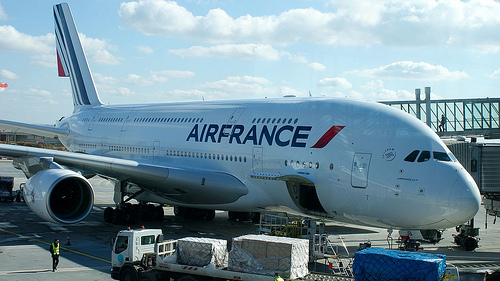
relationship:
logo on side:
[187, 118, 348, 147] [63, 95, 460, 223]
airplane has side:
[1, 0, 481, 238] [63, 95, 460, 223]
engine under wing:
[17, 168, 94, 227] [0, 139, 247, 220]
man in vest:
[50, 235, 63, 275] [50, 243, 61, 257]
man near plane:
[50, 235, 63, 275] [1, 0, 481, 238]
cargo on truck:
[175, 228, 313, 280] [109, 221, 356, 279]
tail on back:
[55, 4, 99, 113] [58, 110, 96, 154]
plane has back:
[1, 0, 481, 238] [58, 110, 96, 154]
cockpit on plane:
[401, 149, 457, 164] [1, 0, 481, 238]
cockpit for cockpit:
[401, 149, 457, 164] [397, 138, 457, 179]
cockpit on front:
[401, 149, 457, 164] [376, 115, 477, 223]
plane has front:
[1, 0, 481, 238] [376, 115, 477, 223]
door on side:
[351, 151, 370, 189] [63, 95, 460, 223]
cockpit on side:
[401, 149, 457, 164] [63, 95, 460, 223]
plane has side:
[1, 0, 481, 238] [63, 95, 460, 223]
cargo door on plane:
[250, 165, 325, 215] [1, 0, 481, 238]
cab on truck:
[113, 223, 163, 268] [109, 221, 356, 279]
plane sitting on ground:
[1, 0, 481, 238] [6, 155, 500, 273]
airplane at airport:
[1, 0, 481, 238] [4, 4, 499, 277]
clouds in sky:
[2, 7, 500, 109] [0, 0, 497, 126]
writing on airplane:
[187, 118, 348, 147] [1, 0, 481, 238]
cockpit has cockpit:
[397, 138, 457, 179] [401, 149, 457, 164]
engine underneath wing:
[17, 168, 94, 227] [0, 139, 247, 220]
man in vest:
[50, 239, 62, 272] [50, 243, 61, 257]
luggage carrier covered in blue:
[348, 244, 451, 278] [354, 249, 454, 276]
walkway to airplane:
[312, 227, 357, 278] [1, 0, 481, 238]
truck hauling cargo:
[109, 221, 356, 279] [175, 228, 313, 280]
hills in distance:
[30, 113, 61, 129] [2, 0, 497, 155]